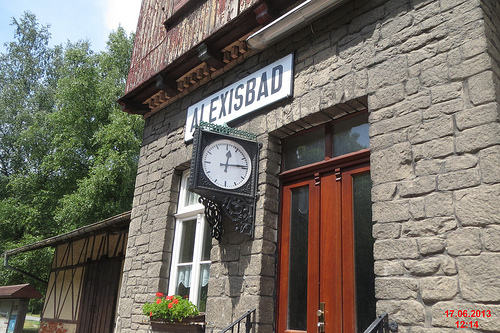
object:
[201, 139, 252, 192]
clock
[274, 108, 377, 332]
door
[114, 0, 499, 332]
building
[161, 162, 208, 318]
window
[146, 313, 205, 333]
planter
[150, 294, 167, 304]
flowers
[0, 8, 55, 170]
trees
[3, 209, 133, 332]
building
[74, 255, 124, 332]
door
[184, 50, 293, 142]
sign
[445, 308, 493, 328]
stamp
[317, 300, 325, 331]
doorknob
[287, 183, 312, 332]
windows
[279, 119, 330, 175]
windows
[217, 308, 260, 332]
railings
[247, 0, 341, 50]
light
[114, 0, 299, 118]
eaves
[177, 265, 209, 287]
curtains